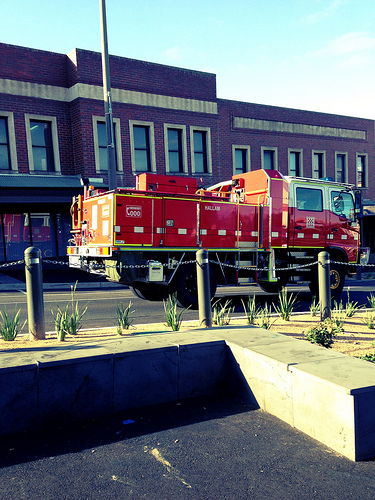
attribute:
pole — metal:
[23, 246, 45, 339]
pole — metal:
[196, 249, 212, 328]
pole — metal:
[317, 251, 330, 320]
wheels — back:
[135, 265, 218, 308]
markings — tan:
[152, 438, 192, 492]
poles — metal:
[21, 247, 213, 334]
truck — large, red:
[91, 149, 359, 312]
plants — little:
[148, 301, 333, 342]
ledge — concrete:
[19, 324, 222, 366]